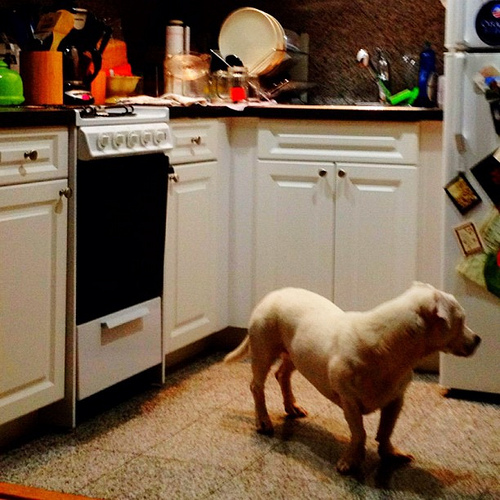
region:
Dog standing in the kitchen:
[225, 161, 481, 466]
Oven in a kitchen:
[46, 55, 202, 392]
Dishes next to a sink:
[151, 5, 445, 115]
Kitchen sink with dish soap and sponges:
[297, 2, 444, 111]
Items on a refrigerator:
[411, 3, 498, 283]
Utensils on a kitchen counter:
[31, 7, 109, 112]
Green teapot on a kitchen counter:
[1, 5, 38, 117]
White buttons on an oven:
[65, 119, 188, 179]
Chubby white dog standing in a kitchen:
[220, 275, 482, 478]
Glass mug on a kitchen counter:
[201, 52, 265, 121]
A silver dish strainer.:
[211, 46, 315, 102]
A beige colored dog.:
[219, 277, 484, 475]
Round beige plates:
[219, 8, 285, 76]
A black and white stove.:
[58, 89, 166, 416]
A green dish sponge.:
[389, 90, 418, 105]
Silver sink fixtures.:
[348, 35, 398, 105]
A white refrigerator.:
[440, 0, 497, 398]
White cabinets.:
[0, 120, 443, 457]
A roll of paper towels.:
[167, 19, 192, 100]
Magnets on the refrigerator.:
[446, 4, 498, 300]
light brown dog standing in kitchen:
[222, 279, 481, 474]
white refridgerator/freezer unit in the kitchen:
[437, 0, 499, 395]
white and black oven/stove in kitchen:
[68, 100, 170, 422]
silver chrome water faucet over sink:
[355, 43, 395, 103]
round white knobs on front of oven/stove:
[95, 128, 166, 151]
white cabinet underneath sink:
[249, 158, 420, 310]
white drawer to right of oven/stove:
[163, 120, 220, 164]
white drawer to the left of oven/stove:
[0, 127, 69, 187]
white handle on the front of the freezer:
[450, 1, 468, 48]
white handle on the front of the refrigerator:
[449, 52, 471, 159]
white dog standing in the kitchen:
[219, 279, 482, 476]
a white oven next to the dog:
[68, 96, 174, 427]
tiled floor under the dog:
[1, 347, 498, 498]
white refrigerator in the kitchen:
[440, 0, 498, 394]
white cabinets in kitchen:
[0, 115, 420, 425]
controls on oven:
[94, 124, 166, 152]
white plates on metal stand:
[217, 5, 287, 70]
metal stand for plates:
[211, 44, 273, 100]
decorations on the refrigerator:
[446, 1, 498, 293]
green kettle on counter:
[0, 58, 25, 103]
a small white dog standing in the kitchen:
[222, 273, 485, 481]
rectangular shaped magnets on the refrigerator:
[444, 168, 483, 258]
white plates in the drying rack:
[212, 5, 289, 77]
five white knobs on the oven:
[96, 128, 170, 153]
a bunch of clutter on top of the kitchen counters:
[0, 5, 446, 111]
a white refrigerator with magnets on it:
[440, 0, 498, 399]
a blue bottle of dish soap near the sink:
[415, 38, 439, 105]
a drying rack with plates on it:
[203, 6, 320, 100]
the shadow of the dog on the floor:
[223, 398, 479, 498]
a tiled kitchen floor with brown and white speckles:
[2, 331, 499, 498]